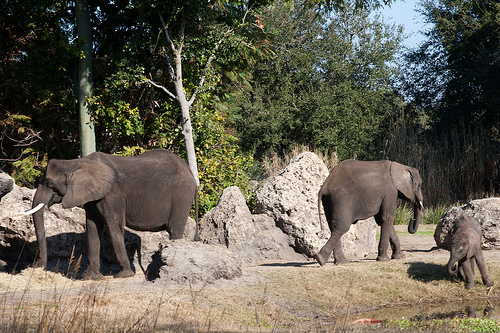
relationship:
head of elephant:
[23, 155, 116, 271] [22, 148, 200, 281]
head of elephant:
[389, 161, 425, 233] [313, 159, 423, 265]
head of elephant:
[448, 230, 468, 276] [446, 216, 493, 287]